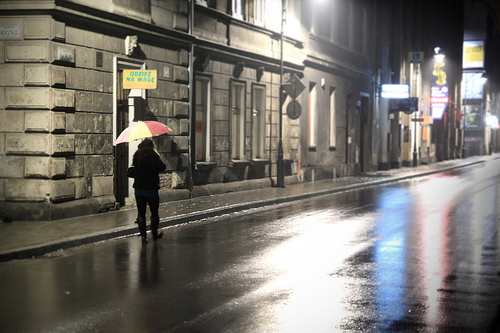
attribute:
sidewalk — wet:
[2, 216, 124, 251]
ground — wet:
[9, 159, 499, 328]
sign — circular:
[285, 93, 308, 122]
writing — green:
[137, 70, 149, 82]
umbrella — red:
[110, 122, 173, 144]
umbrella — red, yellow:
[103, 120, 174, 143]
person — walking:
[131, 138, 167, 243]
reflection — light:
[402, 169, 472, 331]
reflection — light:
[368, 178, 412, 331]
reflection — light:
[209, 202, 381, 332]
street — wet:
[1, 152, 498, 328]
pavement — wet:
[116, 247, 483, 313]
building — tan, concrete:
[0, 1, 374, 215]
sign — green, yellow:
[119, 70, 157, 90]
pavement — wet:
[0, 158, 498, 331]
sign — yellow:
[120, 67, 158, 90]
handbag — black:
[125, 154, 139, 182]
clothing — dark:
[132, 145, 165, 224]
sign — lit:
[376, 78, 414, 99]